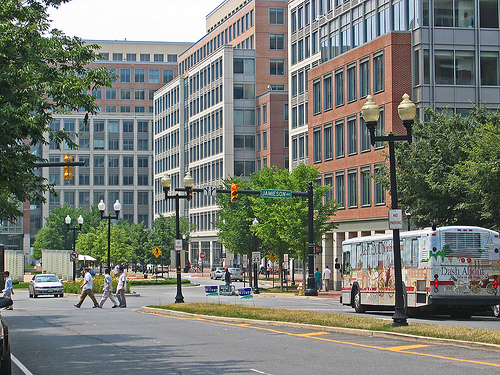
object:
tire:
[351, 282, 361, 307]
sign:
[174, 239, 182, 250]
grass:
[482, 330, 500, 342]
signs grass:
[208, 305, 227, 315]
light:
[97, 199, 105, 211]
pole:
[98, 210, 122, 275]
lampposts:
[387, 141, 409, 327]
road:
[3, 275, 225, 374]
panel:
[308, 31, 417, 236]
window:
[374, 55, 384, 87]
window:
[345, 114, 358, 152]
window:
[323, 122, 334, 163]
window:
[346, 168, 357, 208]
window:
[312, 80, 321, 113]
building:
[283, 0, 498, 290]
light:
[356, 92, 381, 124]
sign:
[389, 208, 403, 229]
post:
[239, 189, 309, 196]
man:
[72, 265, 100, 312]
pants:
[74, 288, 100, 307]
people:
[116, 266, 127, 308]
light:
[395, 92, 418, 118]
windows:
[136, 120, 149, 131]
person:
[98, 268, 117, 307]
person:
[75, 268, 100, 308]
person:
[2, 271, 16, 308]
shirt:
[82, 272, 92, 291]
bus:
[337, 224, 500, 316]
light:
[223, 178, 243, 206]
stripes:
[388, 338, 435, 352]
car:
[27, 273, 66, 301]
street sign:
[260, 188, 293, 198]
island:
[132, 294, 500, 350]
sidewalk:
[312, 287, 343, 297]